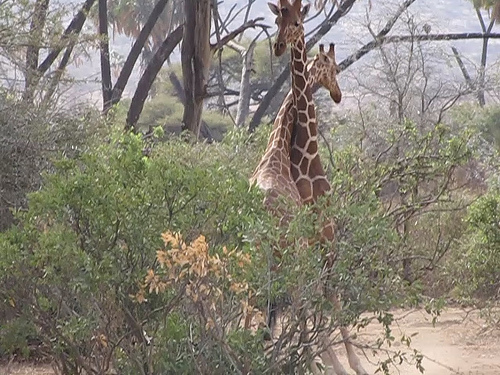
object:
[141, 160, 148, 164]
leaves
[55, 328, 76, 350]
branches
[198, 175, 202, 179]
leaves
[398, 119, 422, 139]
leaf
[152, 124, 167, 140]
leaf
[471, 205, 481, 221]
leaf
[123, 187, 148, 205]
leaf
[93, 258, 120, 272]
leaf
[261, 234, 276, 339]
branch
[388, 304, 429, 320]
branch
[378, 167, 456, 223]
branch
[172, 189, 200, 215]
branch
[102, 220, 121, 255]
branch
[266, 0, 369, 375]
giraffe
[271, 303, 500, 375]
dirt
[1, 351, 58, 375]
dirt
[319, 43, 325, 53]
horn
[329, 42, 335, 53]
horn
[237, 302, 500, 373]
ground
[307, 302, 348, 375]
front legs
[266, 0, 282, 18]
ear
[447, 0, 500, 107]
trees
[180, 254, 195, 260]
leaves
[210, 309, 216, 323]
branches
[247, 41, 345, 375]
giraffe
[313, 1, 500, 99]
tree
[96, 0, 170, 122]
tree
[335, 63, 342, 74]
giraffe ears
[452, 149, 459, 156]
leaves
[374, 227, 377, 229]
leaves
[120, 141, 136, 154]
leaves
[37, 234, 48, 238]
leaves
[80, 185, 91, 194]
leaves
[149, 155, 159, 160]
leaves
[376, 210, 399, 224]
branches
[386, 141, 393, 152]
branches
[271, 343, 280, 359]
branches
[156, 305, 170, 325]
branches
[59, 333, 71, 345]
branches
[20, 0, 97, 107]
trees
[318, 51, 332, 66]
ears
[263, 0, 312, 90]
head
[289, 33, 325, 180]
neck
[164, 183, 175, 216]
branches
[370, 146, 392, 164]
branches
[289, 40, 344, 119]
head